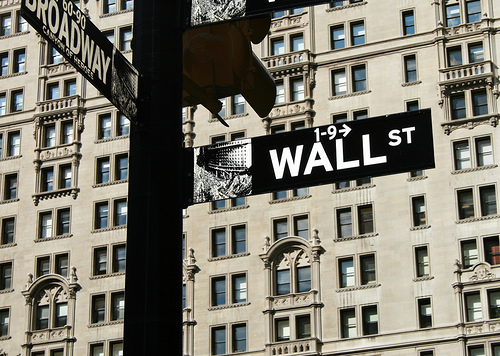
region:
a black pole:
[124, 2, 183, 354]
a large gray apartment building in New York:
[2, 4, 497, 354]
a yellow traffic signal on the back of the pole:
[189, 20, 277, 122]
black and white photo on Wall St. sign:
[197, 141, 253, 203]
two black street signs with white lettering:
[22, 0, 434, 205]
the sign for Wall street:
[252, 107, 434, 209]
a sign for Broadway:
[20, 1, 136, 123]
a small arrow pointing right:
[336, 122, 350, 139]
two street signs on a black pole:
[18, 1, 432, 354]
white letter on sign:
[269, 142, 304, 186]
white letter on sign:
[301, 142, 333, 180]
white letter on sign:
[331, 136, 361, 171]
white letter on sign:
[358, 130, 388, 164]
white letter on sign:
[387, 123, 402, 147]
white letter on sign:
[398, 120, 417, 147]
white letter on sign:
[98, 48, 113, 84]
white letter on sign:
[90, 45, 105, 78]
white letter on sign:
[79, 28, 95, 63]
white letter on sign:
[67, 18, 84, 59]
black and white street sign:
[206, 125, 444, 175]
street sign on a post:
[133, 47, 445, 249]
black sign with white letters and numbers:
[206, 120, 449, 198]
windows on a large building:
[261, 228, 338, 343]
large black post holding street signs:
[126, 7, 192, 312]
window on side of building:
[37, 165, 81, 193]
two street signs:
[26, 0, 442, 228]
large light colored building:
[8, 1, 449, 353]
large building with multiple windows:
[9, 5, 457, 307]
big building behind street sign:
[12, 9, 477, 322]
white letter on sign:
[270, 145, 306, 180]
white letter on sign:
[335, 139, 359, 171]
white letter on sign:
[405, 125, 417, 144]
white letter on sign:
[78, 28, 95, 73]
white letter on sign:
[68, 17, 84, 54]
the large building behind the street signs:
[0, 0, 499, 355]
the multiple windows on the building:
[0, 0, 499, 355]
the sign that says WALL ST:
[180, 107, 435, 207]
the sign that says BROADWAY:
[19, 0, 144, 123]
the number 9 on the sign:
[326, 123, 335, 139]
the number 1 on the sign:
[313, 125, 319, 140]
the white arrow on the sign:
[337, 123, 350, 136]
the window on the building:
[410, 192, 428, 227]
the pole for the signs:
[122, 0, 191, 354]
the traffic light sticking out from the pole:
[182, 10, 277, 127]